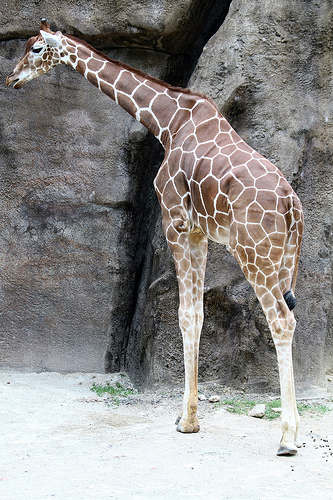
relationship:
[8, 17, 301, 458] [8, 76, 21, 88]
giraffe has mouth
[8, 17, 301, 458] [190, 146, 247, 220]
giraffe has pattern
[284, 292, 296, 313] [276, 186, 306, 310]
end of tail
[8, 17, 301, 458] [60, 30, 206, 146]
giraffe has neck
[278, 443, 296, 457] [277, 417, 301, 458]
hoof on foot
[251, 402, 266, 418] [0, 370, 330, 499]
rock on ground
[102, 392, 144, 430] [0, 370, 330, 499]
grass on ground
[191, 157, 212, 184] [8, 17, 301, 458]
spot on giraffe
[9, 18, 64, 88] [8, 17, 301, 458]
head of giraffe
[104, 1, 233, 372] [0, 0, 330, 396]
crack in rock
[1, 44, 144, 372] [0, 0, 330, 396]
side of rock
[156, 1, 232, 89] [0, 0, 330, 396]
blackness in a rock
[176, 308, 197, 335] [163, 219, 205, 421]
knee of leg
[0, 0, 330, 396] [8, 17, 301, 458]
rock keeping giraffe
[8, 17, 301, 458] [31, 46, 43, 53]
giraffe with eye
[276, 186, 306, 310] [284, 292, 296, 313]
tail with end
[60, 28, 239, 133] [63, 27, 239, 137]
fur along back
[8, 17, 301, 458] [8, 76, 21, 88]
giraffe with mouth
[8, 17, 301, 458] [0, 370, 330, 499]
giraffe on ground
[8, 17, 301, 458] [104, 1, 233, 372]
giraffe in front of crack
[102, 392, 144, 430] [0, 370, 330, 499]
grass at ground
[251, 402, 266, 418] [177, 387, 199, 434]
rock behind foot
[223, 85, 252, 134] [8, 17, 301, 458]
opening behind giraffe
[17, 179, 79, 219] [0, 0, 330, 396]
bump on rock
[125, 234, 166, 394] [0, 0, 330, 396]
edge to rock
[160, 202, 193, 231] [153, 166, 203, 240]
opening in thigh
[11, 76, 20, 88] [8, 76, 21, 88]
lips on mouth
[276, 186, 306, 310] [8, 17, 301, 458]
tail of giraffe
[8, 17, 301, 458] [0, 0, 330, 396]
giraffe by rock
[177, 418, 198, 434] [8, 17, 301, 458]
hoof of giraffe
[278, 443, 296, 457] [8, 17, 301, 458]
hoof of giraffe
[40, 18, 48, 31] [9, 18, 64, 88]
horn on head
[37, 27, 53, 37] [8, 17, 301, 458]
ear of giraffe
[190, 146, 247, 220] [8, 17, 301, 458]
pattern on giraffe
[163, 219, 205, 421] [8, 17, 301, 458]
leg of giraffe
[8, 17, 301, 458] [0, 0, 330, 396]
giraffe standing by rock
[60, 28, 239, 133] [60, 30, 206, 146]
fur on neck